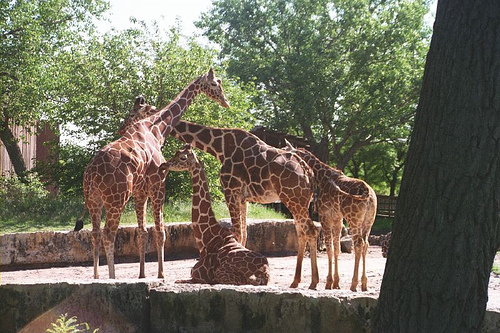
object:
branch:
[0, 0, 115, 102]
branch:
[32, 28, 127, 113]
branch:
[117, 15, 207, 103]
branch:
[200, 13, 312, 137]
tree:
[372, 0, 500, 333]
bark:
[425, 142, 454, 166]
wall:
[0, 231, 70, 272]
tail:
[72, 168, 93, 233]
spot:
[103, 173, 115, 188]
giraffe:
[157, 144, 270, 286]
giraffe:
[72, 66, 230, 280]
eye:
[178, 152, 188, 161]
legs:
[101, 193, 125, 278]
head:
[158, 143, 197, 172]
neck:
[152, 85, 200, 133]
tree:
[0, 0, 110, 186]